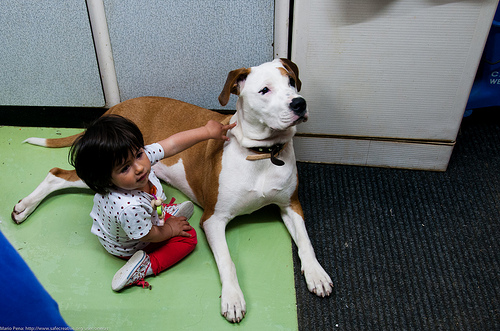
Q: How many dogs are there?
A: One.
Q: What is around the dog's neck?
A: A collar.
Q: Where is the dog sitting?
A: To the right of the child.